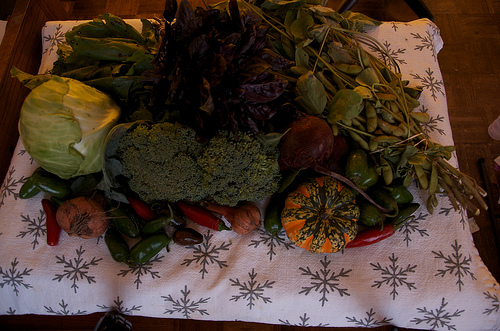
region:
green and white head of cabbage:
[17, 77, 118, 175]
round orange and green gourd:
[284, 174, 361, 251]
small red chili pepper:
[345, 223, 400, 251]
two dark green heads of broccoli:
[123, 126, 282, 206]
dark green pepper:
[125, 228, 170, 267]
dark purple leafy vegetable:
[146, 12, 289, 130]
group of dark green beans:
[362, 102, 404, 137]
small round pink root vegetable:
[52, 194, 107, 239]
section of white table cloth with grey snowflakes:
[0, 243, 499, 326]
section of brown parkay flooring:
[449, 6, 499, 125]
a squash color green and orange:
[276, 172, 364, 259]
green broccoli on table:
[112, 107, 279, 217]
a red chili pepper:
[342, 212, 407, 254]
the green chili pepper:
[101, 207, 166, 267]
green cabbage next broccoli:
[10, 70, 121, 180]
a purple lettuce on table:
[130, 0, 280, 120]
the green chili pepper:
[16, 165, 61, 200]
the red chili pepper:
[35, 192, 62, 245]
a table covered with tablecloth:
[5, 1, 476, 318]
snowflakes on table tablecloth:
[218, 260, 285, 310]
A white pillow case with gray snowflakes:
[4, 19, 499, 329]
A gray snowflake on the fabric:
[231, 264, 276, 310]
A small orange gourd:
[282, 176, 357, 251]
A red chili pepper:
[346, 220, 408, 248]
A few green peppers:
[103, 210, 175, 262]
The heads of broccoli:
[131, 125, 271, 200]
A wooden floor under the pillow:
[0, 0, 499, 225]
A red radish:
[278, 115, 397, 215]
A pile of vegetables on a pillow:
[19, 20, 466, 253]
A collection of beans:
[321, 47, 479, 202]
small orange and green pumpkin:
[281, 175, 365, 255]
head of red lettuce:
[163, 0, 287, 127]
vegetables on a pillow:
[7, 11, 482, 291]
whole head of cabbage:
[15, 76, 120, 181]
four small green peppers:
[98, 205, 175, 275]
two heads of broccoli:
[107, 112, 279, 207]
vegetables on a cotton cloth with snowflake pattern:
[10, 7, 490, 312]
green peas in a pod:
[355, 67, 443, 185]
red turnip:
[272, 111, 348, 176]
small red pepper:
[182, 200, 234, 233]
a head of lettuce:
[22, 89, 124, 181]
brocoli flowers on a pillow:
[112, 123, 283, 222]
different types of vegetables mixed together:
[42, 12, 414, 150]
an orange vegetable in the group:
[290, 178, 366, 275]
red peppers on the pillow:
[24, 197, 406, 292]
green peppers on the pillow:
[102, 202, 174, 269]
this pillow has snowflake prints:
[217, 259, 402, 328]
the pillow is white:
[14, 247, 466, 324]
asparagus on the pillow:
[432, 132, 496, 249]